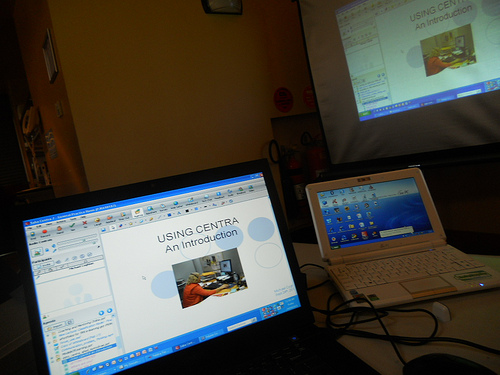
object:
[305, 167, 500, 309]
laptop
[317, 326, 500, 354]
cables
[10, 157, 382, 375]
laptop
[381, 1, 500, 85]
presentation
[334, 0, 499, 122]
screen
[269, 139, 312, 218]
fire extinguisher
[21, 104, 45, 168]
wall phone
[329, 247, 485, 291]
keyboard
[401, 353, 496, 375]
mouse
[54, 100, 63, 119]
switch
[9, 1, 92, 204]
wall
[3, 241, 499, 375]
table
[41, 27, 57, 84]
picture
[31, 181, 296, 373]
website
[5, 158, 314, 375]
monitor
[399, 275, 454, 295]
mouse pad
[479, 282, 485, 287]
power light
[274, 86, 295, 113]
sticker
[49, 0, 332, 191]
wall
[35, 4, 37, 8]
paint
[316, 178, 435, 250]
screen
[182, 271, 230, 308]
woman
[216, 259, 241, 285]
computer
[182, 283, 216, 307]
shirt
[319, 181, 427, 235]
desktop background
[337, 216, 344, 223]
icons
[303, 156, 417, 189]
edge